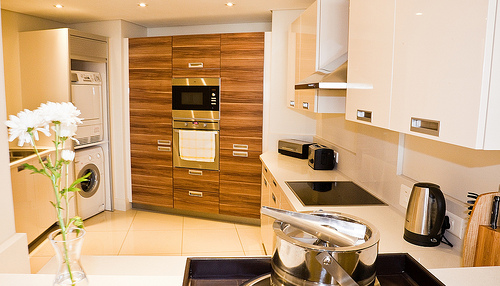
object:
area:
[170, 35, 221, 50]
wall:
[123, 21, 274, 223]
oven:
[169, 76, 221, 129]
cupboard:
[343, 0, 499, 156]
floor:
[26, 206, 262, 271]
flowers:
[2, 101, 97, 283]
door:
[217, 32, 263, 215]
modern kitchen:
[0, 0, 499, 284]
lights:
[135, 1, 147, 10]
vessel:
[47, 225, 92, 284]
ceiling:
[1, 0, 316, 28]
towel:
[179, 130, 218, 163]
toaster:
[307, 144, 335, 170]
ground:
[262, 0, 499, 202]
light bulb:
[52, 4, 66, 10]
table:
[259, 141, 408, 251]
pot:
[261, 206, 383, 286]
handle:
[428, 183, 446, 243]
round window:
[76, 164, 101, 198]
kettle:
[404, 182, 445, 247]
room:
[0, 0, 499, 285]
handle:
[232, 150, 250, 157]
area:
[223, 174, 258, 190]